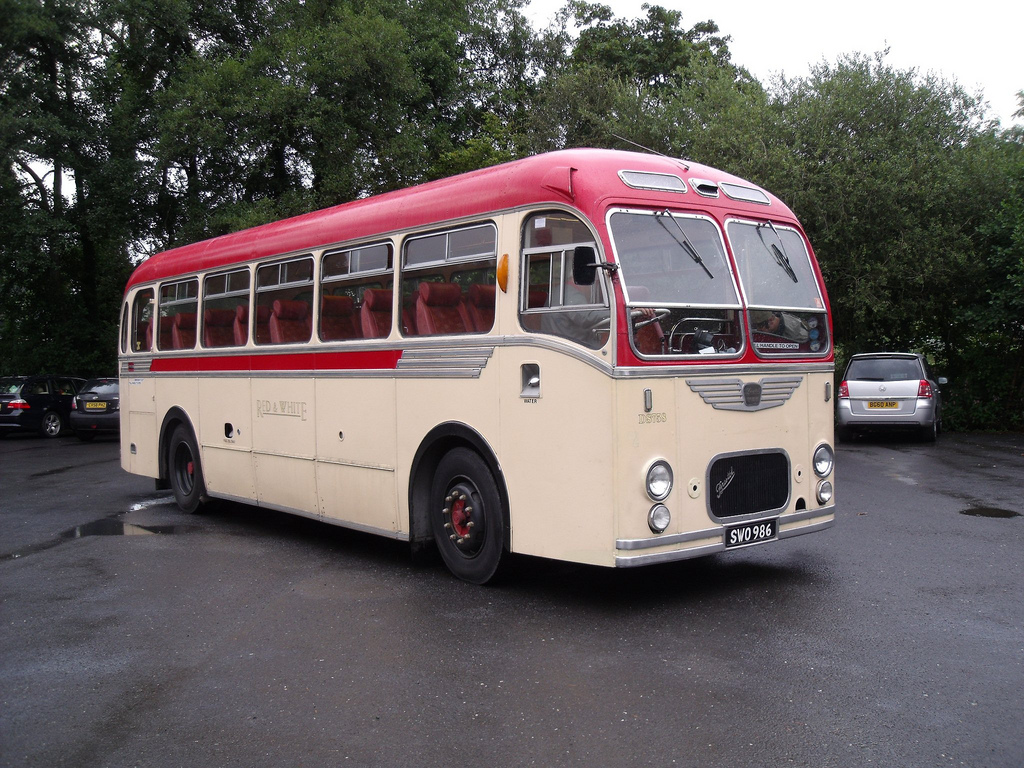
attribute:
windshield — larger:
[601, 199, 751, 372]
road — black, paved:
[3, 430, 1017, 763]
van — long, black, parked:
[0, 372, 94, 446]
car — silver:
[832, 346, 949, 442]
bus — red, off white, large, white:
[111, 130, 840, 591]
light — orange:
[491, 245, 511, 300]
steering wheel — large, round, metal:
[584, 301, 677, 338]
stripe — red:
[143, 346, 409, 375]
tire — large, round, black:
[424, 443, 511, 591]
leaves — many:
[143, 7, 474, 170]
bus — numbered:
[382, 163, 875, 604]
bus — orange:
[40, 173, 853, 446]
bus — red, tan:
[6, 117, 957, 627]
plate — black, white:
[675, 458, 892, 614]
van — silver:
[839, 344, 948, 437]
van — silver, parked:
[835, 344, 950, 442]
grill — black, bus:
[709, 441, 796, 522]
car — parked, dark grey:
[61, 381, 122, 451]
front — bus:
[606, 152, 838, 565]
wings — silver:
[679, 357, 807, 418]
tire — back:
[163, 417, 202, 510]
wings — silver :
[496, 299, 602, 464]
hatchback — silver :
[806, 266, 988, 558]